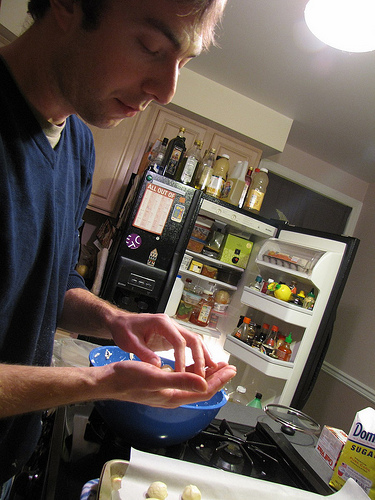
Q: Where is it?
A: This is at the kitchen.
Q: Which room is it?
A: It is a kitchen.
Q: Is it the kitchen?
A: Yes, it is the kitchen.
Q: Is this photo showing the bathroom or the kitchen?
A: It is showing the kitchen.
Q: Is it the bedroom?
A: No, it is the kitchen.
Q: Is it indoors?
A: Yes, it is indoors.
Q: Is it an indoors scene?
A: Yes, it is indoors.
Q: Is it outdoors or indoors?
A: It is indoors.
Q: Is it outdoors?
A: No, it is indoors.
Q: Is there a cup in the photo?
A: No, there are no cups.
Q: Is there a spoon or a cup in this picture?
A: No, there are no cups or spoons.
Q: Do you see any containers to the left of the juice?
A: Yes, there is a container to the left of the juice.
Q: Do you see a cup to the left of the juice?
A: No, there is a container to the left of the juice.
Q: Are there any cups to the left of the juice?
A: No, there is a container to the left of the juice.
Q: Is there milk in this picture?
A: Yes, there is milk.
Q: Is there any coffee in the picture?
A: No, there is no coffee.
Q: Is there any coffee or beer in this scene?
A: No, there are no coffee or beer.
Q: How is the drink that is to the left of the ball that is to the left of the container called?
A: The drink is milk.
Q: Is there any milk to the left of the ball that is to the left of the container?
A: Yes, there is milk to the left of the ball.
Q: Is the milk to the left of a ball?
A: Yes, the milk is to the left of a ball.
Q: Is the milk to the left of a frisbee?
A: No, the milk is to the left of a ball.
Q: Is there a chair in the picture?
A: No, there are no chairs.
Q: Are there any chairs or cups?
A: No, there are no chairs or cups.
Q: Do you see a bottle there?
A: Yes, there is a bottle.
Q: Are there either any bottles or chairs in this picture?
A: Yes, there is a bottle.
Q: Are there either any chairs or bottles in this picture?
A: Yes, there is a bottle.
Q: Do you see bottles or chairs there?
A: Yes, there is a bottle.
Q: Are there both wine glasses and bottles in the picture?
A: No, there is a bottle but no wine glasses.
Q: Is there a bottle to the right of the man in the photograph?
A: Yes, there is a bottle to the right of the man.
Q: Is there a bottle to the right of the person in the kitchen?
A: Yes, there is a bottle to the right of the man.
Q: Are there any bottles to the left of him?
A: No, the bottle is to the right of the man.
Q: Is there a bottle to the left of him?
A: No, the bottle is to the right of the man.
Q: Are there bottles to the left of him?
A: No, the bottle is to the right of the man.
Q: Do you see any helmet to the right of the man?
A: No, there is a bottle to the right of the man.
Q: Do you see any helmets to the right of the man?
A: No, there is a bottle to the right of the man.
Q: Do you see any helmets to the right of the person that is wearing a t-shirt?
A: No, there is a bottle to the right of the man.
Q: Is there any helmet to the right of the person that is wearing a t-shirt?
A: No, there is a bottle to the right of the man.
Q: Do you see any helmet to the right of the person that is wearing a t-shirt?
A: No, there is a bottle to the right of the man.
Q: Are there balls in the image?
A: Yes, there is a ball.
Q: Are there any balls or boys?
A: Yes, there is a ball.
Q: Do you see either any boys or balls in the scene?
A: Yes, there is a ball.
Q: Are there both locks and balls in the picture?
A: No, there is a ball but no locks.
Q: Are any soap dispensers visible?
A: No, there are no soap dispensers.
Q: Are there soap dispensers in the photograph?
A: No, there are no soap dispensers.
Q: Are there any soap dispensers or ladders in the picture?
A: No, there are no soap dispensers or ladders.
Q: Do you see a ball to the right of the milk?
A: Yes, there is a ball to the right of the milk.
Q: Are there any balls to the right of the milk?
A: Yes, there is a ball to the right of the milk.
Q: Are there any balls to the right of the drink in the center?
A: Yes, there is a ball to the right of the milk.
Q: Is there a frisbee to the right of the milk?
A: No, there is a ball to the right of the milk.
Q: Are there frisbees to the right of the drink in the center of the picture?
A: No, there is a ball to the right of the milk.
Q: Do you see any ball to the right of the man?
A: Yes, there is a ball to the right of the man.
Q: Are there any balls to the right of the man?
A: Yes, there is a ball to the right of the man.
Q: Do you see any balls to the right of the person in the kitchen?
A: Yes, there is a ball to the right of the man.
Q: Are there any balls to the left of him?
A: No, the ball is to the right of the man.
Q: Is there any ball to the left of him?
A: No, the ball is to the right of the man.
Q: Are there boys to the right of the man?
A: No, there is a ball to the right of the man.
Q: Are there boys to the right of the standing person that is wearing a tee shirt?
A: No, there is a ball to the right of the man.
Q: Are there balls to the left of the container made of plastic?
A: Yes, there is a ball to the left of the container.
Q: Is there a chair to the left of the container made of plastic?
A: No, there is a ball to the left of the container.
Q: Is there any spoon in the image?
A: No, there are no spoons.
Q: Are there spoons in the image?
A: No, there are no spoons.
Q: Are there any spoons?
A: No, there are no spoons.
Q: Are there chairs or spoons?
A: No, there are no spoons or chairs.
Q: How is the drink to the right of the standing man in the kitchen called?
A: The drink is juice.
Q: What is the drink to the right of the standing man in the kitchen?
A: The drink is juice.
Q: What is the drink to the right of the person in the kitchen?
A: The drink is juice.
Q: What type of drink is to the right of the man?
A: The drink is juice.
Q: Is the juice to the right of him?
A: Yes, the juice is to the right of the man.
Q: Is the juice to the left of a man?
A: No, the juice is to the right of a man.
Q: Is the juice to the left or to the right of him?
A: The juice is to the right of the man.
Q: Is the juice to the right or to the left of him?
A: The juice is to the right of the man.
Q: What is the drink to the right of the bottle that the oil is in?
A: The drink is juice.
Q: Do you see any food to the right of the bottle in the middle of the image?
A: No, there is juice to the right of the bottle.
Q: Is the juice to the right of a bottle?
A: Yes, the juice is to the right of a bottle.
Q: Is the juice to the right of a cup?
A: No, the juice is to the right of a bottle.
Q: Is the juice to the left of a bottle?
A: No, the juice is to the right of a bottle.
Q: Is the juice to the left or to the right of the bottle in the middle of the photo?
A: The juice is to the right of the bottle.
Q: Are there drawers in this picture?
A: No, there are no drawers.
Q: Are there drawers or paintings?
A: No, there are no drawers or paintings.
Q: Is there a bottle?
A: Yes, there is a bottle.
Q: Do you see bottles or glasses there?
A: Yes, there is a bottle.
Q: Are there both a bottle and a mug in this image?
A: No, there is a bottle but no mugs.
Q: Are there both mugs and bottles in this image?
A: No, there is a bottle but no mugs.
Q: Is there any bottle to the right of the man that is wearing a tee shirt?
A: Yes, there is a bottle to the right of the man.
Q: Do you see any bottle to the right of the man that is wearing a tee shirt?
A: Yes, there is a bottle to the right of the man.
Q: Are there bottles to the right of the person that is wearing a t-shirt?
A: Yes, there is a bottle to the right of the man.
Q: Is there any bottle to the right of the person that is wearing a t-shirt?
A: Yes, there is a bottle to the right of the man.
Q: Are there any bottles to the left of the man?
A: No, the bottle is to the right of the man.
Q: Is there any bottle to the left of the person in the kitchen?
A: No, the bottle is to the right of the man.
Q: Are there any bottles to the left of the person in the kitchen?
A: No, the bottle is to the right of the man.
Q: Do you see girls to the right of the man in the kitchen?
A: No, there is a bottle to the right of the man.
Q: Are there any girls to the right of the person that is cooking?
A: No, there is a bottle to the right of the man.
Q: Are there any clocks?
A: No, there are no clocks.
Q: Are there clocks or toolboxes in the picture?
A: No, there are no clocks or toolboxes.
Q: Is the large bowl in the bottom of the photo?
A: Yes, the bowl is in the bottom of the image.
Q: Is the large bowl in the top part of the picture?
A: No, the bowl is in the bottom of the image.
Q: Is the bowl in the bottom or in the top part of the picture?
A: The bowl is in the bottom of the image.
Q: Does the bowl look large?
A: Yes, the bowl is large.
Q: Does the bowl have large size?
A: Yes, the bowl is large.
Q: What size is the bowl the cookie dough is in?
A: The bowl is large.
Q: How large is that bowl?
A: The bowl is large.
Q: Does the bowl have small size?
A: No, the bowl is large.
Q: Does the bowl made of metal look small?
A: No, the bowl is large.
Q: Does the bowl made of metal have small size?
A: No, the bowl is large.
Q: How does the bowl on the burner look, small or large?
A: The bowl is large.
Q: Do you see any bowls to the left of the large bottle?
A: Yes, there is a bowl to the left of the bottle.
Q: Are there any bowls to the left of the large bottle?
A: Yes, there is a bowl to the left of the bottle.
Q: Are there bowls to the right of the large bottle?
A: No, the bowl is to the left of the bottle.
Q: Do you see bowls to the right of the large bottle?
A: No, the bowl is to the left of the bottle.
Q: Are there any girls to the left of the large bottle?
A: No, there is a bowl to the left of the bottle.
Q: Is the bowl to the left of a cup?
A: No, the bowl is to the left of the bottle.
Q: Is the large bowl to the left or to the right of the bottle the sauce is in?
A: The bowl is to the left of the bottle.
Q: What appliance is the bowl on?
A: The bowl is on the stove.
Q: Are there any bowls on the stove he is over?
A: Yes, there is a bowl on the stove.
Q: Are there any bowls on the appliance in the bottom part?
A: Yes, there is a bowl on the stove.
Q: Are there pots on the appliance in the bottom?
A: No, there is a bowl on the stove.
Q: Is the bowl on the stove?
A: Yes, the bowl is on the stove.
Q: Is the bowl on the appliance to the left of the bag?
A: Yes, the bowl is on the stove.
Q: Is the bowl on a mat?
A: No, the bowl is on the stove.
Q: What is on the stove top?
A: The bowl is on the stove top.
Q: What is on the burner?
A: The bowl is on the stove top.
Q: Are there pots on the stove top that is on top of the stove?
A: No, there is a bowl on the stove top.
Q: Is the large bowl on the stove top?
A: Yes, the bowl is on the stove top.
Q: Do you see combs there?
A: No, there are no combs.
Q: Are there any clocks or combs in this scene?
A: No, there are no combs or clocks.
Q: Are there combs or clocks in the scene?
A: No, there are no combs or clocks.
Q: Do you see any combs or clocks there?
A: No, there are no combs or clocks.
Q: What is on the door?
A: The paper is on the door.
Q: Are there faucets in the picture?
A: No, there are no faucets.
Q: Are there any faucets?
A: No, there are no faucets.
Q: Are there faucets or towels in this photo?
A: No, there are no faucets or towels.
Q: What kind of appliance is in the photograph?
A: The appliance is a stove.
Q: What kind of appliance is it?
A: The appliance is a stove.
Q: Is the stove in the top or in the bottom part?
A: The stove is in the bottom of the image.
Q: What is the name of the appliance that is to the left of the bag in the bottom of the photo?
A: The appliance is a stove.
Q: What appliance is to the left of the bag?
A: The appliance is a stove.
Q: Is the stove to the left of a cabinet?
A: No, the stove is to the left of the bag.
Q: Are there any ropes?
A: No, there are no ropes.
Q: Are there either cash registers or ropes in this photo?
A: No, there are no ropes or cash registers.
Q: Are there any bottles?
A: Yes, there is a bottle.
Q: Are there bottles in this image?
A: Yes, there is a bottle.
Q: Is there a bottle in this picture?
A: Yes, there is a bottle.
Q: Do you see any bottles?
A: Yes, there is a bottle.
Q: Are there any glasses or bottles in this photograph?
A: Yes, there is a bottle.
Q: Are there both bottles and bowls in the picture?
A: Yes, there are both a bottle and a bowl.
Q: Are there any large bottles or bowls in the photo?
A: Yes, there is a large bottle.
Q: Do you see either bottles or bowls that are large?
A: Yes, the bottle is large.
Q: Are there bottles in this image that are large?
A: Yes, there is a large bottle.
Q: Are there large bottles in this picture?
A: Yes, there is a large bottle.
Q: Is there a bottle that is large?
A: Yes, there is a bottle that is large.